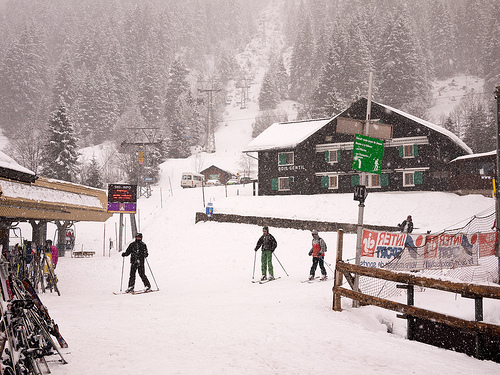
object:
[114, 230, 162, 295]
skier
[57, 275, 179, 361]
hill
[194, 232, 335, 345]
hill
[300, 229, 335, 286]
skier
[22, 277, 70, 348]
skis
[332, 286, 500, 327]
fence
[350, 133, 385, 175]
sign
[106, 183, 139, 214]
sign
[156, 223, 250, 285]
white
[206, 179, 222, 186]
cars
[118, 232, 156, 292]
person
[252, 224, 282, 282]
person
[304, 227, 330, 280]
person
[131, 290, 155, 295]
skis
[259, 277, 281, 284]
skis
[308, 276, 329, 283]
skis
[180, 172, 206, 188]
van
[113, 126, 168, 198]
ski lift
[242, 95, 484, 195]
ski lodge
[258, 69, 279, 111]
pine trees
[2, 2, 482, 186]
mountain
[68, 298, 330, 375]
snow